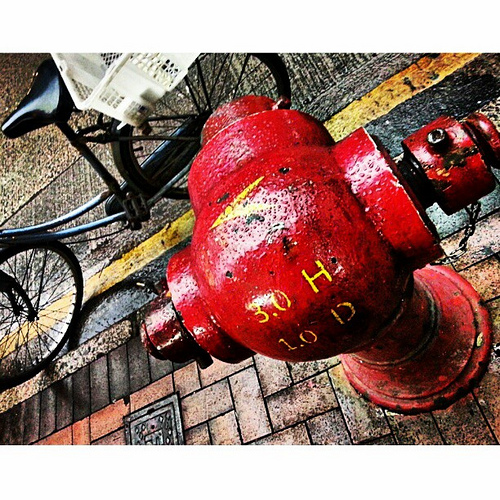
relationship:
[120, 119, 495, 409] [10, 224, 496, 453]
hydrant in sidewalk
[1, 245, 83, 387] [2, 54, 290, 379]
wheel on front of bicycle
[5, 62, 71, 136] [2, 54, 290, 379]
seat of bicycle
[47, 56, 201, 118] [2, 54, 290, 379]
basket in bicycle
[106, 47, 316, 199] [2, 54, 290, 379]
wheel of bicycle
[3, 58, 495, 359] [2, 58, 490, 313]
road with line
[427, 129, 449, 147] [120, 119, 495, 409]
bolt on top of hydrant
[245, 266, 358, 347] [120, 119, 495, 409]
numbers written on hydrant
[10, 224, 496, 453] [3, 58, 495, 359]
sidewalk by road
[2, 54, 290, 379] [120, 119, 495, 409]
bicycle near hydrant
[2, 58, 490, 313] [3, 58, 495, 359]
line on top of road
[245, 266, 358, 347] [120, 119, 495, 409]
numbers on top of hydrant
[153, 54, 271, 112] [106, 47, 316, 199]
spokes in wheel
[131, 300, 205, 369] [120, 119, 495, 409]
valve on side of hydrant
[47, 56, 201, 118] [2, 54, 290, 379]
basket on back of bicycle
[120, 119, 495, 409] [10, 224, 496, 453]
hydrant on top of sidewalk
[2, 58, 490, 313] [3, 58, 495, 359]
line on side of road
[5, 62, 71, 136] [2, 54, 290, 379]
seat on top of bicycle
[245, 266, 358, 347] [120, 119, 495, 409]
numbers on hydrant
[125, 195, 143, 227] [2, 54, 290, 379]
pedal on side of bicycle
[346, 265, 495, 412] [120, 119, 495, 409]
bottom of hydrant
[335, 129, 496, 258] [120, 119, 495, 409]
side of hydrant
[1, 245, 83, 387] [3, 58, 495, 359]
wheel on top of road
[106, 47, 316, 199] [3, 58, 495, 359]
wheel on top of road